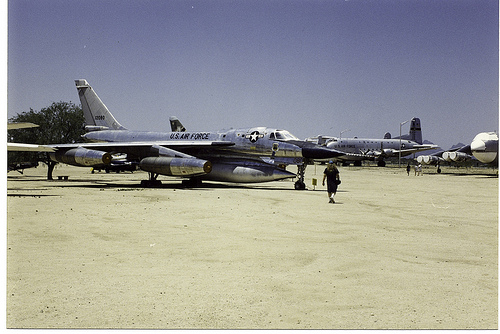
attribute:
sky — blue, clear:
[11, 7, 484, 157]